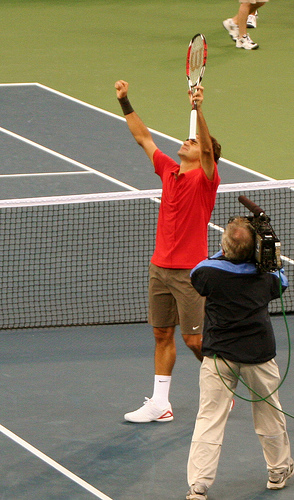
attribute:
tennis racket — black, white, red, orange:
[181, 26, 204, 142]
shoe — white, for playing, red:
[123, 401, 182, 424]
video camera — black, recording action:
[229, 190, 280, 262]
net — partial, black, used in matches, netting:
[2, 176, 292, 329]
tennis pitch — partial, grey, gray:
[1, 82, 291, 499]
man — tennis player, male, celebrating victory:
[112, 78, 234, 428]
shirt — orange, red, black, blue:
[148, 146, 220, 269]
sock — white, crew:
[146, 373, 174, 405]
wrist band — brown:
[117, 98, 133, 116]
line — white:
[1, 126, 141, 193]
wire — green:
[210, 261, 292, 408]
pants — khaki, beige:
[187, 355, 291, 494]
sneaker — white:
[233, 34, 259, 50]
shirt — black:
[188, 254, 290, 363]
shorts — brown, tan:
[146, 267, 206, 336]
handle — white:
[188, 86, 204, 141]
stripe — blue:
[187, 257, 289, 289]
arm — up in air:
[193, 105, 221, 185]